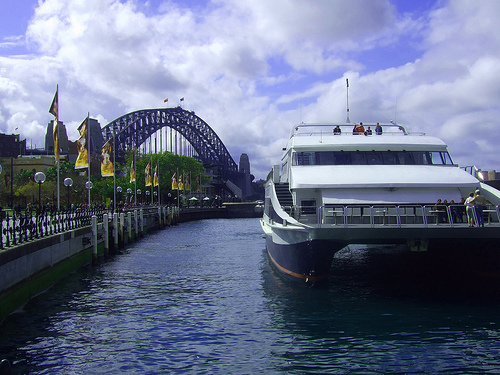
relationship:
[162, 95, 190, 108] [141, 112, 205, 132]
flag on top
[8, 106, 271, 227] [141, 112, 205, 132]
bridge has top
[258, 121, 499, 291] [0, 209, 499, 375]
boat in sea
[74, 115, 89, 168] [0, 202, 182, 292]
flag on bridge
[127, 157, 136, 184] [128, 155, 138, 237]
flag on pole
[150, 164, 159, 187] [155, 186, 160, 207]
flag on pole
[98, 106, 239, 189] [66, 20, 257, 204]
bridge in background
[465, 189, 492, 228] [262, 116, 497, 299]
person on boat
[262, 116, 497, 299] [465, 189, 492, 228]
boat with person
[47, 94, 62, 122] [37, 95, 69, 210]
flag on pole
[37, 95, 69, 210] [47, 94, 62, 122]
pole with flag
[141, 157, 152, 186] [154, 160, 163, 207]
flag on pole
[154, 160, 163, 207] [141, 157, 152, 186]
pole with flag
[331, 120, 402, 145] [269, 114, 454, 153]
people on deck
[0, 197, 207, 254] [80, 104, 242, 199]
metal railing on bridge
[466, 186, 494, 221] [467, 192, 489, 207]
person wearing shirt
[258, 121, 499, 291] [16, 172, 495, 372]
boat in sea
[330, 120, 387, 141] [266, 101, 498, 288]
group on boat